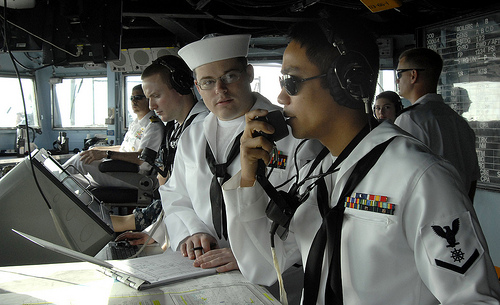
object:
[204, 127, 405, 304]
ties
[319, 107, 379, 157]
neck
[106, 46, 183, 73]
speakers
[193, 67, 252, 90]
glasses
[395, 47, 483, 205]
man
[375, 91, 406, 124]
man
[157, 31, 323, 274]
man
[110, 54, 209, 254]
man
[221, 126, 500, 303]
uniform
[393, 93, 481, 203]
uniform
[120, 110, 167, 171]
uniform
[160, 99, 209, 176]
uniform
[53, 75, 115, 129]
window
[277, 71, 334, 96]
sunglasses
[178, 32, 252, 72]
hat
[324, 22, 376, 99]
headphones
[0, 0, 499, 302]
boat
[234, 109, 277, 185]
hand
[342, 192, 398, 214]
badge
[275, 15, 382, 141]
head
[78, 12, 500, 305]
people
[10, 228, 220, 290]
laptop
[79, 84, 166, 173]
man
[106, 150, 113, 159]
watch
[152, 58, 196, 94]
headphones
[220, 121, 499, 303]
shirt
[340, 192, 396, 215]
stripes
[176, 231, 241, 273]
hands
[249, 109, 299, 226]
speaker phone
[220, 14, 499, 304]
man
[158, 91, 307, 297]
uniform